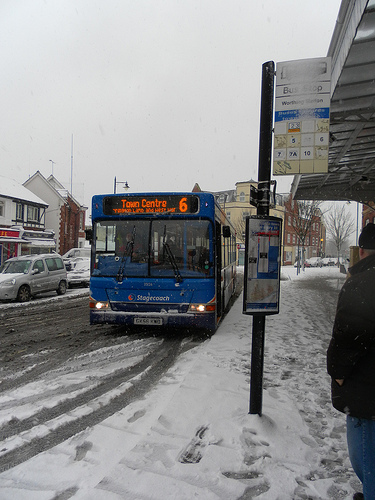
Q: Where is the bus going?
A: Town Centre.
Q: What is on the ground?
A: Snow.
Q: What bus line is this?
A: 6.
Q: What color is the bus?
A: Blue.